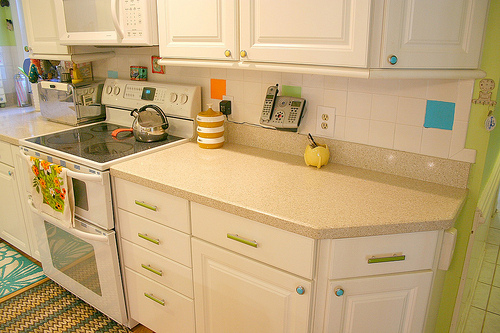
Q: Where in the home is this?
A: Kitchen.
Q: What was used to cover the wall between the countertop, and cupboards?
A: Tile.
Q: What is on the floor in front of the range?
A: Rug.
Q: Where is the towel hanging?
A: Oven handle.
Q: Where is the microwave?
A: Overtop the range.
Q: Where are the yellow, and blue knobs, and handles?
A: Cupboards, and Drawers.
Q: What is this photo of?
A: A room.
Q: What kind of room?
A: A kitchen.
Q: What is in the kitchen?
A: A stove.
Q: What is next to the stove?
A: A counter.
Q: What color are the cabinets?
A: White.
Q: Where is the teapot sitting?
A: On the stove.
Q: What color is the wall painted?
A: Green.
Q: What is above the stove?
A: A microwave.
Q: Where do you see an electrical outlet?
A: On the wall next to the phone.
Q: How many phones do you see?
A: 1.